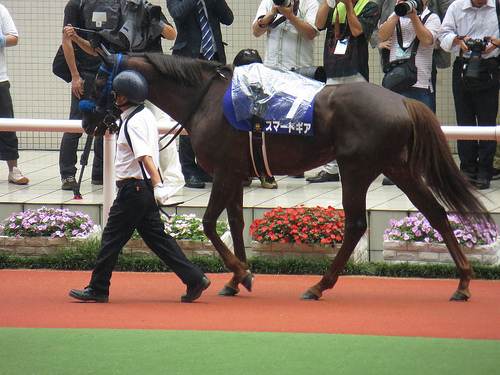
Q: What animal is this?
A: Horse.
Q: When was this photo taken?
A: During the day.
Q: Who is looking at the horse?
A: Photographers.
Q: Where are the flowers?
A: Right of the horse.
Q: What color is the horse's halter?
A: Blue.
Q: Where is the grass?
A: In front of the flowers.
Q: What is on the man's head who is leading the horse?
A: Helmet.